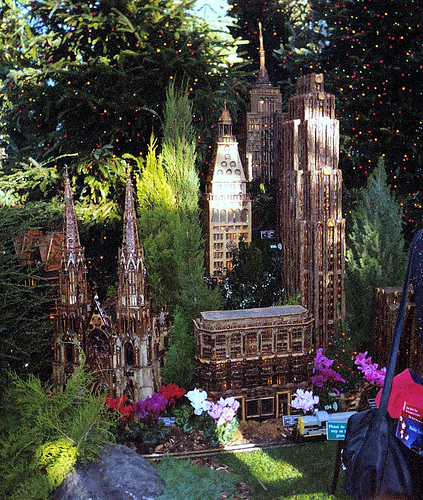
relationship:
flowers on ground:
[286, 345, 387, 411] [2, 388, 421, 498]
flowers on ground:
[66, 383, 250, 444] [41, 363, 387, 491]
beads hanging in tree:
[311, 4, 422, 250] [311, 4, 422, 249]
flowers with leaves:
[163, 378, 240, 437] [174, 412, 216, 451]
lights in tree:
[335, 28, 414, 104] [224, 7, 409, 199]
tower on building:
[217, 95, 235, 143] [199, 92, 256, 295]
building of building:
[51, 163, 112, 399] [103, 166, 176, 405]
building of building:
[103, 166, 176, 405] [103, 166, 176, 405]